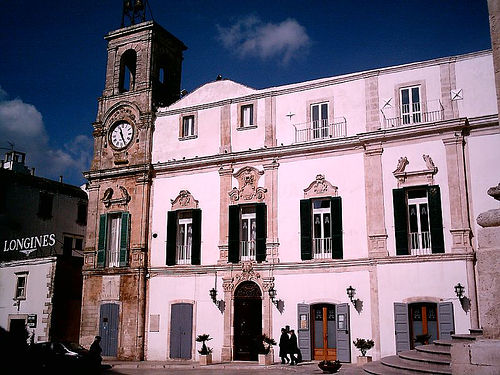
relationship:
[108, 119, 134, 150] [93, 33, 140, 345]
clock on tower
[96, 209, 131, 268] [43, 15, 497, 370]
window on building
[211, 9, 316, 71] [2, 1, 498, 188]
cloud in sky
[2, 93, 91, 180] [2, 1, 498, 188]
cloud in sky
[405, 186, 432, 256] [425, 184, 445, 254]
window with shutter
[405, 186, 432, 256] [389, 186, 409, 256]
window with shutter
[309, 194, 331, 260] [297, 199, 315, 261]
window with shutter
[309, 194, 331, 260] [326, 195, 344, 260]
window with shutter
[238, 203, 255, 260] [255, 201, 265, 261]
window with shutter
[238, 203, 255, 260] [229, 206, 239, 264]
window with shutter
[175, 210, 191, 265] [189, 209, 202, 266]
window with shutter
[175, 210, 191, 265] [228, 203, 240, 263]
window with shutter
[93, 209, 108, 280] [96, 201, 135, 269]
shutters on window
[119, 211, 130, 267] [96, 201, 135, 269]
green shutter on window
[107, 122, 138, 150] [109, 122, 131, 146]
clock with face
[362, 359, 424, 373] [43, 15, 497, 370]
step near building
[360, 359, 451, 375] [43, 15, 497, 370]
step near building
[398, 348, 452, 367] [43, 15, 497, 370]
step near building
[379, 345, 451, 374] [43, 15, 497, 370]
step near building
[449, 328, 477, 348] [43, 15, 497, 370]
step near building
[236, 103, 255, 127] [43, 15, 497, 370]
window on building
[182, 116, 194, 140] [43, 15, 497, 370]
window on building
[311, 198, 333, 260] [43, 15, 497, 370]
window on building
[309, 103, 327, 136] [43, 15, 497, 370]
window on building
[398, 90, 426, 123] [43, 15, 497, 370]
window on building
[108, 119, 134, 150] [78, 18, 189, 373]
clock on tower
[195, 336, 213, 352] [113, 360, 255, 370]
plant near sidewalk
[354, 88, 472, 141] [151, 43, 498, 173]
balcony on floor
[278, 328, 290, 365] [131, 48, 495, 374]
people walking in front of building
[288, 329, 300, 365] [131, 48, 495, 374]
people walking in front of building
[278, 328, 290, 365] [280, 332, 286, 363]
people wearing black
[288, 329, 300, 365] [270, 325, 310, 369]
people wearing people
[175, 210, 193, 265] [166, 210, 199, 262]
window has black shutter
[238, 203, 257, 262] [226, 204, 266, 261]
window has black shutter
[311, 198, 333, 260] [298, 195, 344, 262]
window has black shutter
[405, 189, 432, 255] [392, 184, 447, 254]
window has black shutter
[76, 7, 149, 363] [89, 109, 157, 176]
tower has clock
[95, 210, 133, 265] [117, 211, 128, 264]
window has green shutter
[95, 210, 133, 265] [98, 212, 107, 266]
window has green shutter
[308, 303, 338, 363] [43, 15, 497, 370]
door leading to building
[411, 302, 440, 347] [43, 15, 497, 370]
door leading to building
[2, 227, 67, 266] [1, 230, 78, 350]
sign over building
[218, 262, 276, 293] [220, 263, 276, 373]
scrollwork over doorway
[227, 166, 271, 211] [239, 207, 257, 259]
scrollwork over window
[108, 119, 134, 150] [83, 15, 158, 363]
clock on tower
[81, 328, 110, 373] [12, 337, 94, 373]
man by car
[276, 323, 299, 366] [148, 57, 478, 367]
people walking by building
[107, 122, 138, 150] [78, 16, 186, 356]
clock on building